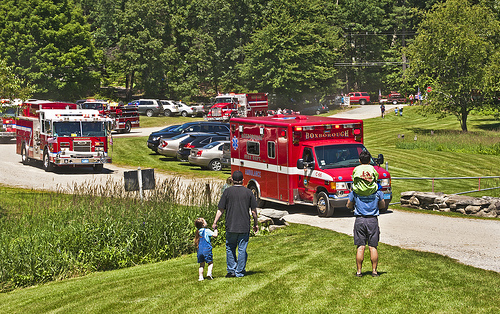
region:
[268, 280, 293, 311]
The grass is green.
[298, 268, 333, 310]
The grass is green.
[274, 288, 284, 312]
The grass is green.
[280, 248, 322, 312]
The grass is green.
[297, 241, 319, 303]
The grass is green.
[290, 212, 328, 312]
The grass is green.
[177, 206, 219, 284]
child wearing blue overalls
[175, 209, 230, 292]
child with long dark hair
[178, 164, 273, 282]
man wearing black hat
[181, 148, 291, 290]
man wearing black pullover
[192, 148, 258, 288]
man wearing blue jeans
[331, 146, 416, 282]
man carrying child on his shoulders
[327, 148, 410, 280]
man wearing blue pullover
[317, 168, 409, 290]
man wearing gray shorts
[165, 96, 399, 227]
bright red emergency vehicle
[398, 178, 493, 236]
very large rock wall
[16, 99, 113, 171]
red and white fire truck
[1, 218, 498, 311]
Lush cut green grass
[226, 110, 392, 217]
A red and white ambulance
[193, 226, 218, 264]
blue and light blue outfit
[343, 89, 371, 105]
A black and red pickup truck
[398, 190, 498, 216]
Small light brown rock wall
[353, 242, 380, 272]
big bulging swollen calves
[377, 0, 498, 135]
large lush green tree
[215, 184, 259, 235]
large wide black shirt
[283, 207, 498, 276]
white gravel type road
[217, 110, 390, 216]
a fire rescue truck driving up a road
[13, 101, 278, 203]
a fire truck is behind the fire rescue truck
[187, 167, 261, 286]
a man is walking with a child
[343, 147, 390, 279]
a man has a child on his shoulders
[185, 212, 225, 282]
the little girl has a ponytail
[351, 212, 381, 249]
the man is wearing gray shorts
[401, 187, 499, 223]
a rock wall is next to the road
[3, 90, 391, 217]
red emergency vehicles are on the road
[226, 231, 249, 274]
the man is wearing blue jeans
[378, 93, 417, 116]
spectators are watching the vehicles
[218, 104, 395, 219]
red emergency truck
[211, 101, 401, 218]
emergency truck has a white stripe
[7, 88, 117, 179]
fire fighter truck in the road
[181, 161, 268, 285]
man with a kid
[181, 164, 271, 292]
man holds a kid with left hand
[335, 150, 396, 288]
man carry a kid on his shoulders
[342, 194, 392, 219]
tee shirt is blue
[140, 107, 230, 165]
four cars parking on the grass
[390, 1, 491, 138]
tree in the middle of a field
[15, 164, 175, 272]
weeds on side of green grass